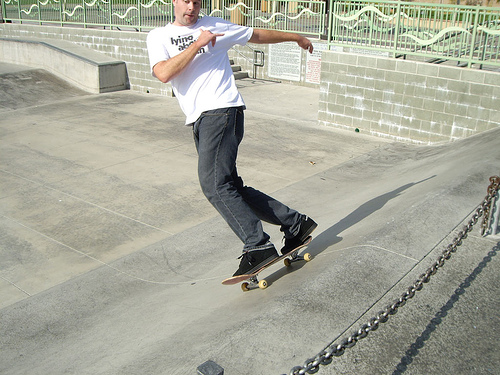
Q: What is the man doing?
A: Skateboarding.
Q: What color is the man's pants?
A: Grey.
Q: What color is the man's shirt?
A: White.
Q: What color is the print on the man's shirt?
A: Black.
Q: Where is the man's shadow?
A: On the ramp.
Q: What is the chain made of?
A: Metal.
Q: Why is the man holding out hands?
A: For balance.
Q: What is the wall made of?
A: Bricks.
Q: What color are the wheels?
A: Yellow.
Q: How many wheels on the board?
A: Four.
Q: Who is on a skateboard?
A: A man with a white t-shirt.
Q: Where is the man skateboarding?
A: In a skate park.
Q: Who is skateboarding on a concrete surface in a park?
A: A man.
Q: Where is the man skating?
A: On a ramp.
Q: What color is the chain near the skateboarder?
A: Silver.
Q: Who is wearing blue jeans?
A: A man.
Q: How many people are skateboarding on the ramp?
A: One.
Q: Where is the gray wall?
A: Behind the skateboarder.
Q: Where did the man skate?
A: At the skatepark.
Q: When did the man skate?
A: During the day.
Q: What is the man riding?
A: A skateboard.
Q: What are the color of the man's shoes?
A: Black.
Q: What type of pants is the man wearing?
A: He is wearing jeans.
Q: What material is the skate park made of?
A: Concrete.